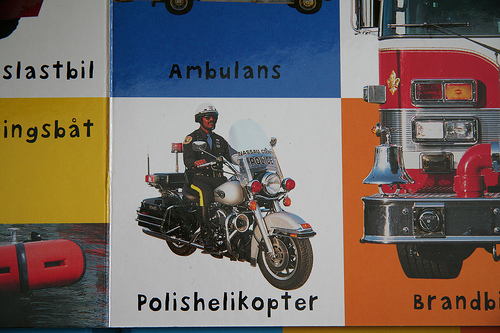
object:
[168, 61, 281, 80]
ambulans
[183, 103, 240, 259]
police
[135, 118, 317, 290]
motorcycle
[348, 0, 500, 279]
fire truck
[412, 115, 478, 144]
headlights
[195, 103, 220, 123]
helmet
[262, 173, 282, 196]
headlights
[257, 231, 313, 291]
front wheel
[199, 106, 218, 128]
head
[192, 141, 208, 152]
rearview mirror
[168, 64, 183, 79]
letter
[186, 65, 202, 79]
letter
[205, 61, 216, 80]
letter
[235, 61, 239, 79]
letter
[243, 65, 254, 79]
letter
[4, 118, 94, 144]
writing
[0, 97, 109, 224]
square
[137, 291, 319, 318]
writing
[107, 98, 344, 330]
square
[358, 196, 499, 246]
bumper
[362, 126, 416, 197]
bell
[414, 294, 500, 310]
writing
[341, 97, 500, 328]
square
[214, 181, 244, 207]
gas tank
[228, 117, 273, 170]
windshield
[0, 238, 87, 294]
sea tube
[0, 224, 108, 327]
water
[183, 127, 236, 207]
uniform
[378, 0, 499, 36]
window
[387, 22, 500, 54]
window wiper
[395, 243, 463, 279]
tire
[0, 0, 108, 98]
squares